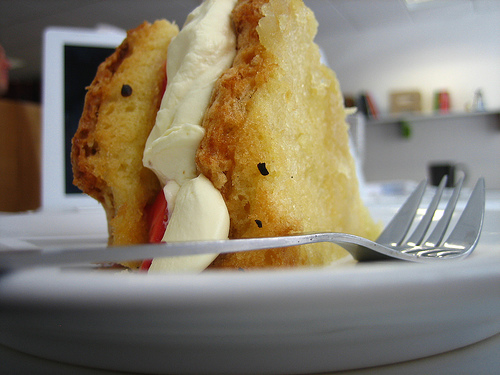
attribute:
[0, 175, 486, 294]
fork — shiny, silver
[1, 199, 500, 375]
plate — white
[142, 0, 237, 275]
cream — white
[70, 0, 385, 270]
food — cooked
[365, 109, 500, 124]
shelf — blurry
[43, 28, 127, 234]
laptop — white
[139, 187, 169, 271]
strawberry — red